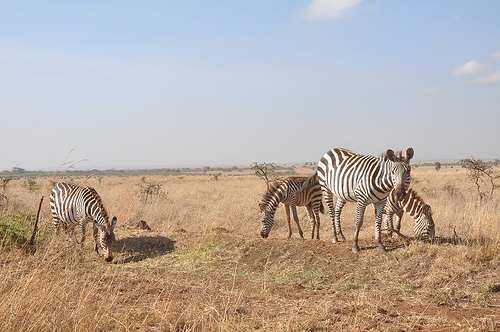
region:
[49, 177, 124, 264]
a zebra eating grass alone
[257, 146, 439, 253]
a group of three zebras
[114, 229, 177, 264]
the shadow of a zebra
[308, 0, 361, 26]
a cloud on the ski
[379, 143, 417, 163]
the ears of a zebra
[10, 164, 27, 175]
a rock mountain in the back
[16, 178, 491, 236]
a lot of dry grass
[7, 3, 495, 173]
blue skies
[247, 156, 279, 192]
a tree behind a zebra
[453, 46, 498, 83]
a group of clouds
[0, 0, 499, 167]
Clear, blue sky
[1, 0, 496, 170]
sky with little clouds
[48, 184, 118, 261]
small zebra by itself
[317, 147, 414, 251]
bigger Zebra in the middle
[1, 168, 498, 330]
grassy ground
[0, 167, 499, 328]
grassy, brown, dried ground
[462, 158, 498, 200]
small, brown tree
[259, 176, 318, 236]
Zebra eating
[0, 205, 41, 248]
small patch of green grass on the left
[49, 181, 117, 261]
small zebra eating on the left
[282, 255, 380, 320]
The ground is brown.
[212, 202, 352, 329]
The ground is brown.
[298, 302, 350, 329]
The ground is brown.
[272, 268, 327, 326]
The ground is brown.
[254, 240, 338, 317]
The ground is brown.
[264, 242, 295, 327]
The ground is brown.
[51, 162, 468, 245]
Zebras in the field.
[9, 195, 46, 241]
A branch sticking up from ground.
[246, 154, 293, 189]
The tree has no leaves.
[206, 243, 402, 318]
/the grass is brown and green.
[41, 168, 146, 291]
The zebra is blak and white.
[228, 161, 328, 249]
Zebra eating grass.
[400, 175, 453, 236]
Zebra with his head in the grass.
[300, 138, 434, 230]
This zebra is bigger than the others.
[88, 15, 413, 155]
The sky is blue and clear.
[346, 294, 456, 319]
Patches of dirt in the grass.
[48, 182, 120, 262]
zebra eating grass in the desert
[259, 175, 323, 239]
smaller zebra behind the largest one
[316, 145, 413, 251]
largest zebra in the group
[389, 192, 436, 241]
another small zebra eating from the ground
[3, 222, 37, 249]
a small patch of green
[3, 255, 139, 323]
dried brown desert grass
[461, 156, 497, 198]
a tree growing in the desert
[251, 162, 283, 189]
a small tree growing in the desert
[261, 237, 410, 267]
barren ground under the zebras' feet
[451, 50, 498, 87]
a cloud in the blue sky